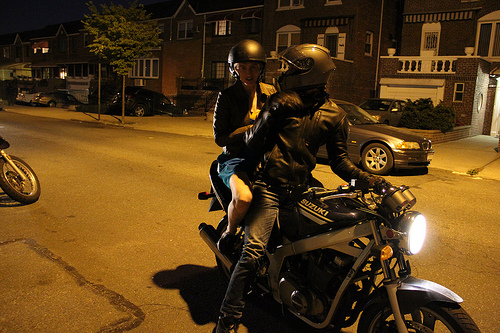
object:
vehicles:
[32, 92, 85, 108]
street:
[1, 226, 138, 329]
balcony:
[379, 56, 479, 76]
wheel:
[134, 106, 145, 117]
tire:
[357, 292, 481, 332]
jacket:
[242, 90, 372, 191]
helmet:
[276, 44, 336, 91]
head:
[275, 43, 336, 92]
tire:
[0, 155, 42, 204]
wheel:
[48, 101, 56, 107]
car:
[358, 98, 409, 127]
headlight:
[394, 211, 426, 256]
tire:
[362, 143, 393, 174]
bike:
[0, 136, 41, 202]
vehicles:
[316, 99, 435, 175]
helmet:
[227, 39, 267, 78]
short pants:
[218, 158, 245, 189]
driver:
[216, 43, 395, 333]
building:
[378, 0, 500, 144]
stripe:
[405, 11, 472, 22]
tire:
[216, 215, 247, 284]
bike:
[197, 159, 481, 333]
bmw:
[103, 86, 178, 117]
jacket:
[212, 80, 278, 154]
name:
[300, 199, 329, 216]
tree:
[81, 0, 163, 124]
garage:
[379, 76, 476, 143]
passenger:
[212, 40, 279, 253]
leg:
[218, 158, 253, 231]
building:
[0, 0, 381, 116]